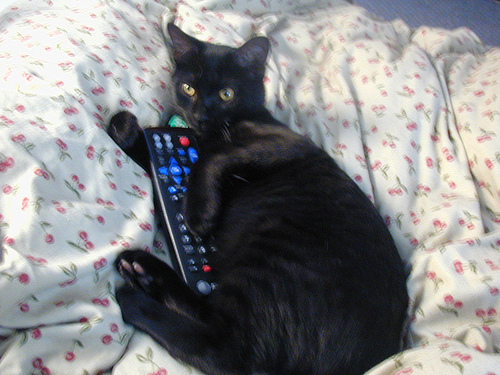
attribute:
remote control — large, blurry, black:
[138, 116, 226, 304]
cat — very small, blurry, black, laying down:
[105, 22, 418, 374]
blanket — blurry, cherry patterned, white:
[2, 1, 498, 372]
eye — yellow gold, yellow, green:
[217, 87, 236, 103]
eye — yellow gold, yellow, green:
[180, 80, 196, 97]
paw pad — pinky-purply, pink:
[134, 262, 142, 275]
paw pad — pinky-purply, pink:
[122, 259, 134, 275]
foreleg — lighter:
[189, 123, 312, 224]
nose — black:
[193, 109, 210, 124]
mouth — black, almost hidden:
[191, 121, 208, 135]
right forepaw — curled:
[109, 108, 140, 153]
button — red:
[179, 136, 192, 147]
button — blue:
[169, 165, 183, 179]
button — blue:
[188, 147, 199, 166]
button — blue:
[177, 147, 187, 159]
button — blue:
[168, 186, 178, 196]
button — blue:
[159, 166, 171, 174]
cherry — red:
[91, 86, 105, 100]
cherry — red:
[101, 69, 113, 77]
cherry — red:
[78, 98, 87, 106]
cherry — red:
[62, 107, 78, 116]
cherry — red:
[69, 53, 79, 59]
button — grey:
[196, 279, 218, 299]